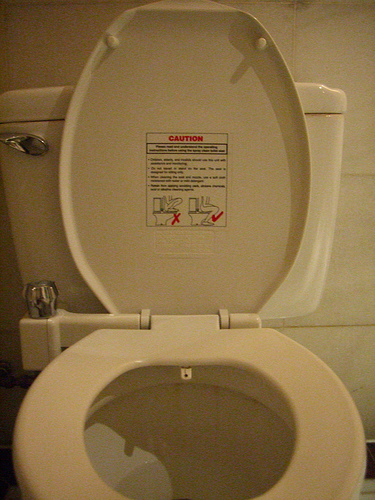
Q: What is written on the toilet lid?
A: Instructions.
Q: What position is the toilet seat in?
A: Down.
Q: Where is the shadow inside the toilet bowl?
A: All around.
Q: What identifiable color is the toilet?
A: White.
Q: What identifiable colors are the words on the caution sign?
A: Black and red.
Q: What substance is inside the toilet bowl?
A: Water.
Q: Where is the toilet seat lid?
A: Up.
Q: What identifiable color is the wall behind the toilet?
A: White.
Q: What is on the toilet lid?
A: Sticker.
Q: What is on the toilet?
A: Seat.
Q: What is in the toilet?
A: Shadow.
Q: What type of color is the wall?
A: White.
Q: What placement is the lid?
A: Up.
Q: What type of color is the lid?
A: White.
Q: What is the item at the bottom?
A: Seat.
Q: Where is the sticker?
A: On the toilet lid.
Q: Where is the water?
A: In the bowl.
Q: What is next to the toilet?
A: The knob.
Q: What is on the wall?
A: Tiles.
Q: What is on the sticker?
A: Writing.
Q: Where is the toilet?
A: The bathroom.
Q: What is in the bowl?
A: Water.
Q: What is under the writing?
A: Pictures.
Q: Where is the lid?
A: On top of the toilet.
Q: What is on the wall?
A: Tile.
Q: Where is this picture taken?
A: Bathroom.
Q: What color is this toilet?
A: White.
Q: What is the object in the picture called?
A: Toilet.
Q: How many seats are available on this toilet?
A: One.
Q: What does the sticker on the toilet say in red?
A: Caution.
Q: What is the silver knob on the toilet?
A: To flush.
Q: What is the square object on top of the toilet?
A: Water tank.